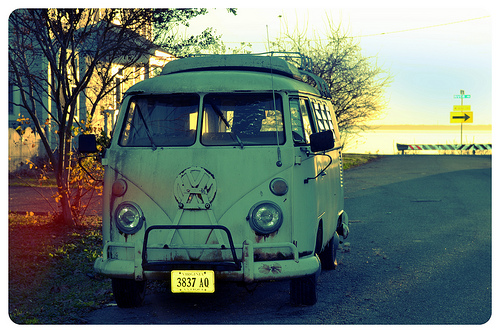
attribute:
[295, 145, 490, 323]
pavement — black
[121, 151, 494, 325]
pavement — black 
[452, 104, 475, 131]
sign — yellow, street sign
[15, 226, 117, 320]
bed — flower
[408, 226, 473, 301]
pavement — black 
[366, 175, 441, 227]
pavement — black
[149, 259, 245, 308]
license plate — yellow 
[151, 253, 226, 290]
plate — number plate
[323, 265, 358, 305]
pavement — black 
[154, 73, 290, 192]
mirror — rear mirror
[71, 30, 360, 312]
van — teal